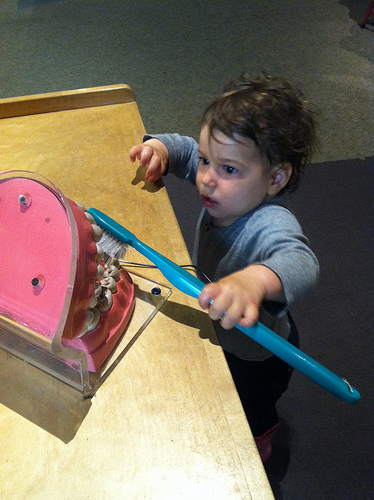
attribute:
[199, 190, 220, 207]
lips — pink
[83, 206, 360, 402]
tooth brush — blue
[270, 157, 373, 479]
carpet — dark , gray 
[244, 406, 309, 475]
shoe — pink 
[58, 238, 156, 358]
seeth — big 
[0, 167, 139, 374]
teeth — plastic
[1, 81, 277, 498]
table — wooden 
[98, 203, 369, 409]
toothbrush — blue, giant 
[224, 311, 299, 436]
pants — black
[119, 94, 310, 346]
child — small 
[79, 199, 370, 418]
tooth brush — large, blue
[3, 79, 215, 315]
table — tan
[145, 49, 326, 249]
kid — little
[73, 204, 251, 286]
toothbrush — big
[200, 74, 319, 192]
hair — brown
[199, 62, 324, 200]
hair — brown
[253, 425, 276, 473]
socks — pink